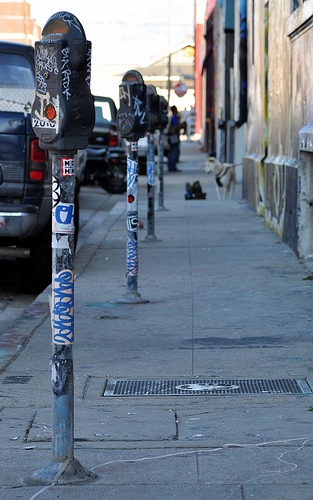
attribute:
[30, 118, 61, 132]
numbers — black 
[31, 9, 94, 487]
parking meter — black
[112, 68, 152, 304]
parking meter — black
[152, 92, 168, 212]
parking meter — black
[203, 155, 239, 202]
dog — white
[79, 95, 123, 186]
car — black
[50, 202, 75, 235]
sticker — blue, white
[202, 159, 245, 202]
dog — white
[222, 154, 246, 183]
harness — black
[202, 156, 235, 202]
dog — brown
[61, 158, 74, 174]
letterig — black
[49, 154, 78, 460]
post — metallic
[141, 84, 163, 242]
parking meter — black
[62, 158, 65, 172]
background — white 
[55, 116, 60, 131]
background — white 